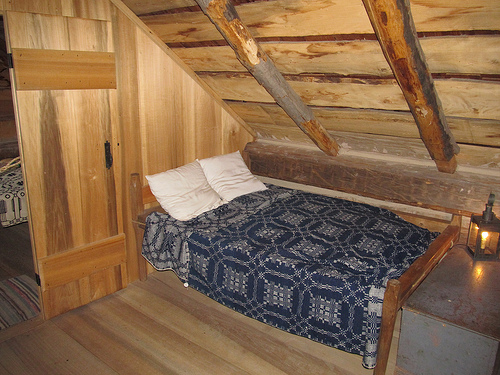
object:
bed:
[138, 174, 461, 374]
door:
[1, 11, 142, 329]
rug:
[0, 273, 41, 328]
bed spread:
[139, 181, 441, 368]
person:
[113, 298, 198, 356]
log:
[194, 0, 339, 157]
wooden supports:
[193, 1, 456, 174]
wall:
[113, 1, 497, 276]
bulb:
[464, 192, 499, 262]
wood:
[10, 48, 114, 90]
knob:
[107, 154, 113, 165]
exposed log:
[361, 0, 457, 174]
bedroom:
[1, 1, 497, 374]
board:
[0, 0, 498, 177]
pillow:
[145, 150, 268, 221]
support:
[38, 233, 127, 294]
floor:
[1, 222, 401, 375]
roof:
[118, 0, 500, 177]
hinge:
[5, 53, 12, 69]